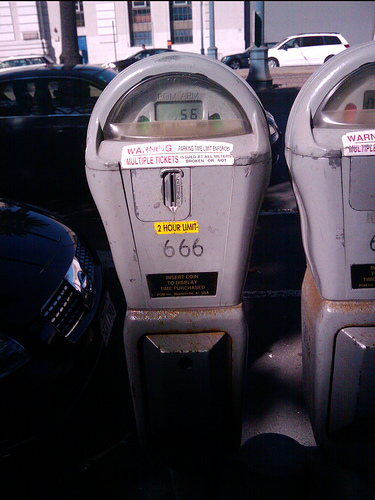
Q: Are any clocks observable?
A: No, there are no clocks.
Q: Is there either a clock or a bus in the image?
A: No, there are no clocks or buses.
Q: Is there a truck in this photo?
A: No, there are no trucks.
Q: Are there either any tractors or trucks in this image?
A: No, there are no trucks or tractors.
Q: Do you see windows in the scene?
A: Yes, there is a window.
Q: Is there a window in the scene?
A: Yes, there is a window.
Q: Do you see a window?
A: Yes, there is a window.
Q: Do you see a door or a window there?
A: Yes, there is a window.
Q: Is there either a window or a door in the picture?
A: Yes, there is a window.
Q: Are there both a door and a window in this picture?
A: No, there is a window but no doors.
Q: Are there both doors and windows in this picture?
A: No, there is a window but no doors.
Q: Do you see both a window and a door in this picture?
A: No, there is a window but no doors.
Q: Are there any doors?
A: No, there are no doors.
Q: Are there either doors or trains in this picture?
A: No, there are no doors or trains.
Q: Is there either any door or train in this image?
A: No, there are no doors or trains.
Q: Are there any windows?
A: Yes, there is a window.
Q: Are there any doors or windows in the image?
A: Yes, there is a window.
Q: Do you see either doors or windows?
A: Yes, there is a window.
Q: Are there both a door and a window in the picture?
A: No, there is a window but no doors.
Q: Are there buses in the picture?
A: No, there are no buses.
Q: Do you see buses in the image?
A: No, there are no buses.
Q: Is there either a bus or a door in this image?
A: No, there are no buses or doors.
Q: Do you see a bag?
A: No, there are no bags.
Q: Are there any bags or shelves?
A: No, there are no bags or shelves.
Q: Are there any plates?
A: Yes, there is a plate.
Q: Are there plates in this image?
A: Yes, there is a plate.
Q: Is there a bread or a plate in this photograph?
A: Yes, there is a plate.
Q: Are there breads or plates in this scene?
A: Yes, there is a plate.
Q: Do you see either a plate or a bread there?
A: Yes, there is a plate.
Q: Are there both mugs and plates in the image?
A: No, there is a plate but no mugs.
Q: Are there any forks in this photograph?
A: No, there are no forks.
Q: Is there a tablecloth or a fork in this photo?
A: No, there are no forks or tablecloths.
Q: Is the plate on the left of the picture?
A: Yes, the plate is on the left of the image.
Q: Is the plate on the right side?
A: No, the plate is on the left of the image.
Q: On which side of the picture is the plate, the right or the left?
A: The plate is on the left of the image.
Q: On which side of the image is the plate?
A: The plate is on the left of the image.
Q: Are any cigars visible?
A: No, there are no cigars.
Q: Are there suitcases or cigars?
A: No, there are no cigars or suitcases.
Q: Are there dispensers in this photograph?
A: No, there are no dispensers.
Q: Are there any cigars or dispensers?
A: No, there are no dispensers or cigars.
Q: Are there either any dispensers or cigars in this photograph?
A: No, there are no dispensers or cigars.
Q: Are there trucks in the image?
A: No, there are no trucks.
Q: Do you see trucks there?
A: No, there are no trucks.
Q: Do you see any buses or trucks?
A: No, there are no trucks or buses.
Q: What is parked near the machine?
A: The car is parked near the machine.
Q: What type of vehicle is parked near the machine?
A: The vehicle is a car.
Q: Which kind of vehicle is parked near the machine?
A: The vehicle is a car.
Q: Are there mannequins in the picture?
A: No, there are no mannequins.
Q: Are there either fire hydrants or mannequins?
A: No, there are no mannequins or fire hydrants.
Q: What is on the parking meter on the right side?
A: The sticker is on the parking meter.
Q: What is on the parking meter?
A: The sticker is on the parking meter.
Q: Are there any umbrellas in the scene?
A: No, there are no umbrellas.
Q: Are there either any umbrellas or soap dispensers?
A: No, there are no umbrellas or soap dispensers.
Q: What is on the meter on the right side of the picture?
A: The sticker is on the meter.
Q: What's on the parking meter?
A: The sticker is on the meter.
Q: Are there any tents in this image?
A: No, there are no tents.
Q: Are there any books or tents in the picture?
A: No, there are no tents or books.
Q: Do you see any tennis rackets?
A: No, there are no tennis rackets.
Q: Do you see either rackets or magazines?
A: No, there are no rackets or magazines.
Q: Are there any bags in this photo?
A: No, there are no bags.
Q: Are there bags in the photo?
A: No, there are no bags.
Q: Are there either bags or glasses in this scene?
A: No, there are no bags or glasses.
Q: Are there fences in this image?
A: No, there are no fences.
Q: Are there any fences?
A: No, there are no fences.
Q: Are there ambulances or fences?
A: No, there are no fences or ambulances.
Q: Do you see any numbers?
A: Yes, there are numbers.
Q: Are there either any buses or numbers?
A: Yes, there are numbers.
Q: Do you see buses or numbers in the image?
A: Yes, there are numbers.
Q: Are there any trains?
A: No, there are no trains.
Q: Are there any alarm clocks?
A: No, there are no alarm clocks.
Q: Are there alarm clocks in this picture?
A: No, there are no alarm clocks.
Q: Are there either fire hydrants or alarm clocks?
A: No, there are no alarm clocks or fire hydrants.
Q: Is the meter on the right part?
A: Yes, the meter is on the right of the image.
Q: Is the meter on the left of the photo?
A: No, the meter is on the right of the image.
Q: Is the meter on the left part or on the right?
A: The meter is on the right of the image.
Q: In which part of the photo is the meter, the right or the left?
A: The meter is on the right of the image.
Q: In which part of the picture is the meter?
A: The meter is on the right of the image.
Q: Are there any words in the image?
A: Yes, there are words.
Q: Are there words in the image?
A: Yes, there are words.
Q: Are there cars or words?
A: Yes, there are words.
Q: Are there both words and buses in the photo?
A: No, there are words but no buses.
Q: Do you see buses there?
A: No, there are no buses.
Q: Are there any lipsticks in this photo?
A: No, there are no lipsticks.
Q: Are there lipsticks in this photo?
A: No, there are no lipsticks.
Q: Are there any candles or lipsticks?
A: No, there are no lipsticks or candles.